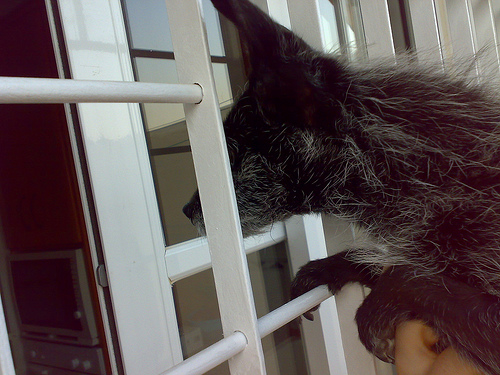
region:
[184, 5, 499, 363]
black and gray dog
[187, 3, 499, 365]
black and gray dog looking in a window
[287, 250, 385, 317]
dog's front paw on a white rail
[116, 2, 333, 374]
glass window with white trim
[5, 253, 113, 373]
built-in oven in kitchen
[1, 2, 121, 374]
kitchen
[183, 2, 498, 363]
black and gray dog looking through window into the kitchen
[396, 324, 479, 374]
hand holding the dog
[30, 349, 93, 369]
knobs on the oven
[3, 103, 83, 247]
cabinet above the oven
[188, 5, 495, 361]
dog with wirey fur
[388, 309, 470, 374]
fingers under dog paw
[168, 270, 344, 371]
paw on white pole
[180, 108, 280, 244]
dog looking through window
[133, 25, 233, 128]
light reflection on glass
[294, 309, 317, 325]
toenails on dog paw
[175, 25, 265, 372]
white board holding posts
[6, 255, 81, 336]
square screen on monitor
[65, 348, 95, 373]
two knobs on device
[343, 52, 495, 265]
black and white fur on dog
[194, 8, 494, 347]
black and grey dog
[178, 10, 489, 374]
dog being held by person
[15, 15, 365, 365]
white bars on window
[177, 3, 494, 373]
black and gray dog looking through window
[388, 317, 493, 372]
hand of person holding dog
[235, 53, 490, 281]
long hair of black and white dog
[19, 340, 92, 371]
white knobs on appliance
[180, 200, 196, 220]
black nose of the dog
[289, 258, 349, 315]
dog's black paw on white bar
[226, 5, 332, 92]
erect ear of black and gray dog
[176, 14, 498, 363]
black and white dog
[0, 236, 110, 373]
large television on metal stand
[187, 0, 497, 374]
dog held by human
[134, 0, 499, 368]
dog looking into window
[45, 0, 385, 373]
white painted window trim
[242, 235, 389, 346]
dog paw curved around wood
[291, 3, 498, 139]
white outdoor trim by window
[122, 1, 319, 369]
reflection in outdoor window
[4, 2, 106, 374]
orange painted wall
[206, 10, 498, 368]
black dog with some white hair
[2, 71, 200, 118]
The bar on the stairs is white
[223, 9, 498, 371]
The dog is black and gray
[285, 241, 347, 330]
The paw of the dog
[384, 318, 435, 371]
The finger of the person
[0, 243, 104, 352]
A device against the wall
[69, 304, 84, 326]
A knob on the device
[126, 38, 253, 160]
A reflection of the bars in the window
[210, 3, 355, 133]
The ear of the dog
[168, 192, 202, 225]
The nose of the dog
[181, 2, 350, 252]
The head of the dog